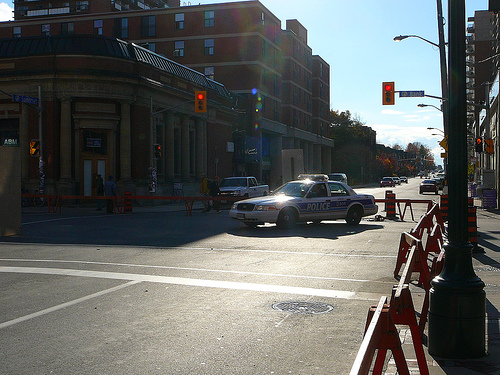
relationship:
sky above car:
[168, 0, 486, 149] [229, 177, 377, 227]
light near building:
[193, 86, 210, 119] [10, 6, 334, 200]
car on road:
[229, 177, 377, 227] [0, 170, 446, 375]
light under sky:
[193, 86, 210, 119] [168, 0, 486, 149]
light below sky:
[193, 86, 210, 119] [168, 0, 486, 149]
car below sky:
[229, 177, 377, 227] [168, 0, 486, 149]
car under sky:
[229, 177, 377, 227] [168, 0, 486, 149]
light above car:
[193, 86, 210, 119] [229, 177, 377, 227]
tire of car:
[276, 192, 303, 244] [228, 157, 376, 242]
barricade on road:
[354, 207, 443, 357] [148, 282, 361, 361]